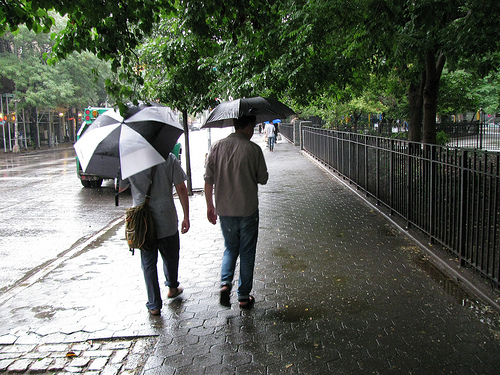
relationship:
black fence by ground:
[311, 115, 496, 277] [0, 269, 499, 375]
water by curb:
[75, 225, 116, 244] [2, 205, 123, 290]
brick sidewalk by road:
[260, 228, 397, 372] [0, 107, 202, 257]